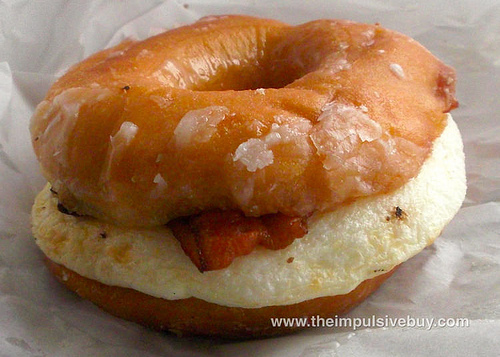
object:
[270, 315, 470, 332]
website address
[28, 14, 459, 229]
donut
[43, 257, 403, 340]
donut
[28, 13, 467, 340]
sandwich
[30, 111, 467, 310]
cooked egg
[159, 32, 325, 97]
hole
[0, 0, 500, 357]
photo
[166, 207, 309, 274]
bacon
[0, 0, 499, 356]
food wrapper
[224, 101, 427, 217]
glaze